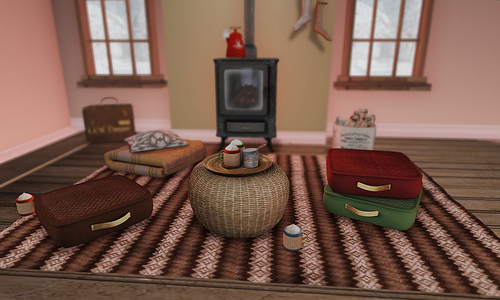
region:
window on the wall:
[330, 1, 435, 97]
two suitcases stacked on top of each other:
[315, 140, 440, 235]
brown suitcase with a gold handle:
[27, 170, 157, 245]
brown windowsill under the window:
[326, 67, 436, 92]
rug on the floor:
[1, 135, 496, 292]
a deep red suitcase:
[325, 141, 425, 196]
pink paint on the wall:
[53, 0, 165, 133]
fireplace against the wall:
[198, 0, 293, 150]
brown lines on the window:
[349, 1, 420, 74]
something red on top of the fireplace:
[220, 20, 249, 60]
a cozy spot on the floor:
[3, 20, 486, 299]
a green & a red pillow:
[321, 134, 433, 236]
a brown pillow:
[26, 180, 158, 244]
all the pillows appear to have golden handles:
[81, 182, 390, 237]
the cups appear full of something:
[213, 134, 263, 174]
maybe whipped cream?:
[216, 131, 247, 166]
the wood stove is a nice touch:
[195, 45, 296, 148]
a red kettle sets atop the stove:
[213, 19, 250, 64]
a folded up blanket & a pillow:
[108, 121, 214, 188]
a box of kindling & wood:
[328, 105, 391, 145]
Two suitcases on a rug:
[309, 124, 445, 244]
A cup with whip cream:
[276, 215, 318, 257]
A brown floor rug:
[338, 229, 498, 298]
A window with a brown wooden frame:
[334, 10, 469, 102]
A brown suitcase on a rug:
[19, 169, 167, 256]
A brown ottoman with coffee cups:
[176, 135, 301, 248]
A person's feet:
[284, 1, 339, 46]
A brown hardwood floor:
[432, 138, 499, 190]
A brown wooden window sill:
[65, 68, 180, 91]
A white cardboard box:
[323, 113, 395, 152]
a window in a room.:
[337, 0, 437, 92]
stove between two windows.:
[206, 51, 295, 148]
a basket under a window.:
[80, 91, 155, 153]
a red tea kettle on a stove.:
[217, 28, 268, 63]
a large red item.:
[324, 137, 449, 200]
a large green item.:
[321, 180, 436, 232]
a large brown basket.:
[177, 128, 298, 239]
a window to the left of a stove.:
[71, 0, 171, 87]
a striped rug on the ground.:
[0, 138, 498, 291]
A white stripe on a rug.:
[134, 193, 205, 279]